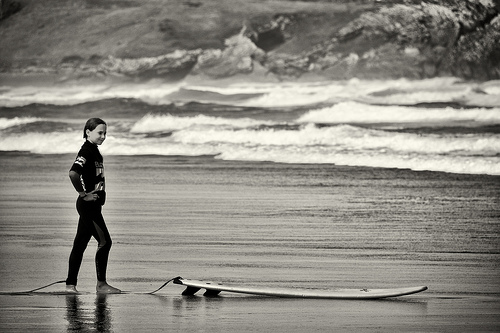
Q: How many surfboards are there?
A: 1.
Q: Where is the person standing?
A: On beach.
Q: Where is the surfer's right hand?
A: On her hip.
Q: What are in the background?
A: Waves.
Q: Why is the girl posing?
A: For a photo.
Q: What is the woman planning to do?
A: Surf.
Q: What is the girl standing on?
A: Sand.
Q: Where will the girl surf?
A: In water.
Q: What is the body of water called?
A: Ocean.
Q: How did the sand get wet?
A: From water.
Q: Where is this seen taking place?
A: On beach.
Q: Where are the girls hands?
A: On hips.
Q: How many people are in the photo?
A: One.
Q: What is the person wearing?
A: Wetsuit.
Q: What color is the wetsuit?
A: Black.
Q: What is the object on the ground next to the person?
A: Surfboard.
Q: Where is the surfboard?
A: Sand.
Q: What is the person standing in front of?
A: Ocean.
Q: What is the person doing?
A: Standing.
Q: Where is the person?
A: The ocean.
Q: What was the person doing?
A: Surfing.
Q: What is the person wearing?
A: A wet suit.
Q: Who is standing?
A: A woman.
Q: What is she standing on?
A: The sand.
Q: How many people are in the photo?
A: One.